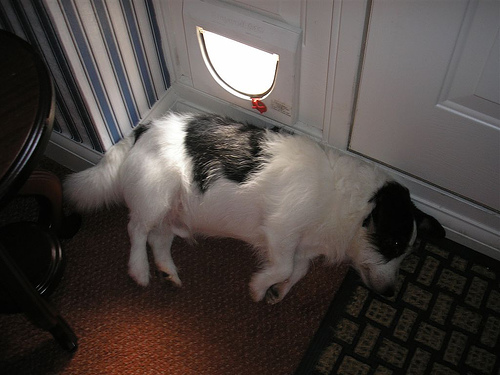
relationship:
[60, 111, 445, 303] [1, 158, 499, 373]
dog sleeping on floor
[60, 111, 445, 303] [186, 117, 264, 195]
dog has a black patch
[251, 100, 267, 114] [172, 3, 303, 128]
lock on pet door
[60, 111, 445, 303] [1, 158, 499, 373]
dog laying on floor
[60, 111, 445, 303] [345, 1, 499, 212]
dog next to door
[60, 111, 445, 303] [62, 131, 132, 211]
dog has a tail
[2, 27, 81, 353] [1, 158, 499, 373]
table on floor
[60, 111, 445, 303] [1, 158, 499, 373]
dog on floor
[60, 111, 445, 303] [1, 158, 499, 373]
dog lying on floor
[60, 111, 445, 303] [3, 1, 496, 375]
dog in house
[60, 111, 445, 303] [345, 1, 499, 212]
dog lying near door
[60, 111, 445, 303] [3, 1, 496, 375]
dog guarding house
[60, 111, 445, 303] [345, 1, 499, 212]
dog waiting near door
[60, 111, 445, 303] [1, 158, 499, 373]
dog resting on floor